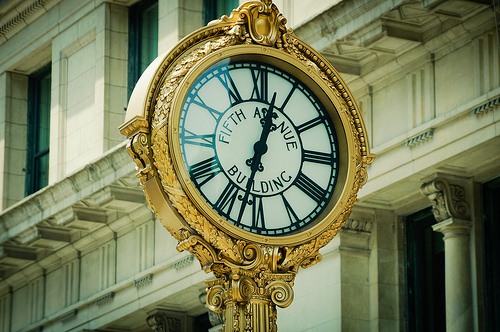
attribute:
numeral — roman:
[212, 62, 257, 112]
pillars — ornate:
[421, 169, 483, 307]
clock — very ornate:
[182, 43, 354, 243]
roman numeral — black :
[184, 156, 221, 187]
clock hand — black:
[244, 92, 278, 223]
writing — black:
[219, 106, 297, 191]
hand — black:
[239, 81, 330, 211]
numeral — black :
[189, 90, 226, 123]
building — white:
[0, 2, 497, 329]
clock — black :
[171, 97, 329, 212]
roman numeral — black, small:
[295, 170, 325, 200]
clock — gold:
[122, 2, 377, 327]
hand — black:
[237, 158, 257, 233]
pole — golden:
[205, 265, 292, 330]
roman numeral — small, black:
[303, 148, 334, 168]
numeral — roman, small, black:
[296, 174, 331, 201]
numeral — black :
[175, 123, 215, 148]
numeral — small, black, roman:
[245, 187, 271, 234]